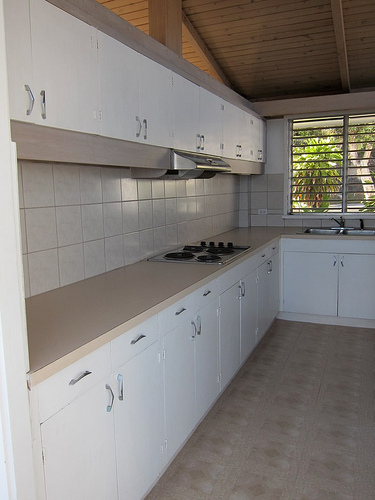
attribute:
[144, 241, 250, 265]
stove — silver, black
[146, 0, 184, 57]
beam — support 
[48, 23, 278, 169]
cabinets — white, colored, lower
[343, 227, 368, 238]
sink — steel 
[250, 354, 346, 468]
floor — colored , light 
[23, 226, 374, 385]
beige countertop — colored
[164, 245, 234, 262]
burners — stove , electric , four 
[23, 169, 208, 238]
tile wall — white 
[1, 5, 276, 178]
cabinet — white, colored, upper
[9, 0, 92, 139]
cabinet — White 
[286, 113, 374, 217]
blinds — open, pair 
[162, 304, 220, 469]
cabinet — second, lower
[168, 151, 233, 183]
hood — silver 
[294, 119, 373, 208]
blinds — horizontal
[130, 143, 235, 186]
hood — silver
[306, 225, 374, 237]
double sink — double , steel , stainless 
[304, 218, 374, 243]
sink — steel 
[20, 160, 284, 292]
tile wall — beige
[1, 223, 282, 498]
cabinet — first, lower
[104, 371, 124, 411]
silver handles — silver , pair 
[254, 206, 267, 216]
outlet — white 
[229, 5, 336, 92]
ceiling — light, colored, wooden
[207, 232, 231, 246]
knobs — cooktop 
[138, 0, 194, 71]
pillar — wooden 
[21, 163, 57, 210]
tile — beige, colored, backsplash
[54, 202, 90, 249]
tile — beige, colored, backsplash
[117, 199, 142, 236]
tile — beige, colored, backsplash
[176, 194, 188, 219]
tile — beige, colored, backsplash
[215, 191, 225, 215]
tile — beige, colored, backsplash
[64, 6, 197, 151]
cabinet — upper , second 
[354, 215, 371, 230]
sprayer — water 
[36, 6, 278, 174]
cupboards — white 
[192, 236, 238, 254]
knobs — black , few 